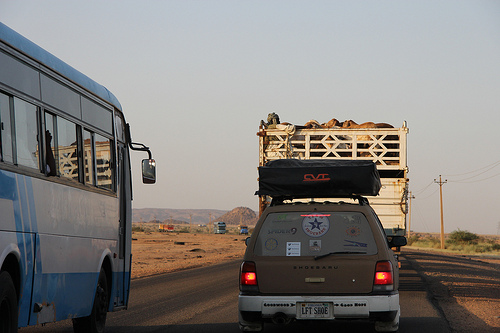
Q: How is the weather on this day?
A: It is clear.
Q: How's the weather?
A: It is clear.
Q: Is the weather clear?
A: Yes, it is clear.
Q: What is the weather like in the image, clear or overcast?
A: It is clear.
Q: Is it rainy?
A: No, it is clear.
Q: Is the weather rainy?
A: No, it is clear.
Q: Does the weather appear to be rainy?
A: No, it is clear.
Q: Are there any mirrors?
A: Yes, there is a mirror.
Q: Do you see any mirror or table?
A: Yes, there is a mirror.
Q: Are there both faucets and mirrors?
A: No, there is a mirror but no faucets.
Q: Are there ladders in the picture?
A: No, there are no ladders.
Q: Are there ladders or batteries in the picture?
A: No, there are no ladders or batteries.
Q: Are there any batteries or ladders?
A: No, there are no ladders or batteries.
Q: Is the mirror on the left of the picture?
A: Yes, the mirror is on the left of the image.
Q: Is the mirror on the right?
A: No, the mirror is on the left of the image.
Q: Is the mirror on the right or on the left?
A: The mirror is on the left of the image.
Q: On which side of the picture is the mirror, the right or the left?
A: The mirror is on the left of the image.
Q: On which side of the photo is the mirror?
A: The mirror is on the left of the image.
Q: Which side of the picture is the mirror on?
A: The mirror is on the left of the image.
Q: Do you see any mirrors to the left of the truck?
A: Yes, there is a mirror to the left of the truck.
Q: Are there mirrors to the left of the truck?
A: Yes, there is a mirror to the left of the truck.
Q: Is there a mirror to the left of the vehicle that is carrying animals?
A: Yes, there is a mirror to the left of the truck.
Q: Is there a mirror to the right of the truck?
A: No, the mirror is to the left of the truck.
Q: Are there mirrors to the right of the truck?
A: No, the mirror is to the left of the truck.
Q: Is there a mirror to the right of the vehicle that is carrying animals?
A: No, the mirror is to the left of the truck.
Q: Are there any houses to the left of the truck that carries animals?
A: No, there is a mirror to the left of the truck.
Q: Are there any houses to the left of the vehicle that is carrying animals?
A: No, there is a mirror to the left of the truck.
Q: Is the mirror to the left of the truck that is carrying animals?
A: Yes, the mirror is to the left of the truck.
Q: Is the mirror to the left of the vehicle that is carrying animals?
A: Yes, the mirror is to the left of the truck.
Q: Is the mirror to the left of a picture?
A: No, the mirror is to the left of the truck.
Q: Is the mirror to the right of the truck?
A: No, the mirror is to the left of the truck.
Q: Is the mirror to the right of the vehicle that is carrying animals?
A: No, the mirror is to the left of the truck.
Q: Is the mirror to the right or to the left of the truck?
A: The mirror is to the left of the truck.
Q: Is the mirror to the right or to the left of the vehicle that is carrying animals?
A: The mirror is to the left of the truck.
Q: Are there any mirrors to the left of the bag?
A: Yes, there is a mirror to the left of the bag.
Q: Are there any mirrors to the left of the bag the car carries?
A: Yes, there is a mirror to the left of the bag.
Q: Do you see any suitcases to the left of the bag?
A: No, there is a mirror to the left of the bag.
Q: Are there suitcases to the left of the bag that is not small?
A: No, there is a mirror to the left of the bag.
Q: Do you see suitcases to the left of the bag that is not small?
A: No, there is a mirror to the left of the bag.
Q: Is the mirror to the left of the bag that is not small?
A: Yes, the mirror is to the left of the bag.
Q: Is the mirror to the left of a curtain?
A: No, the mirror is to the left of the bag.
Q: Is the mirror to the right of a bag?
A: No, the mirror is to the left of a bag.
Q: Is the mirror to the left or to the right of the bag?
A: The mirror is to the left of the bag.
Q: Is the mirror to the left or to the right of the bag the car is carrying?
A: The mirror is to the left of the bag.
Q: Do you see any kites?
A: No, there are no kites.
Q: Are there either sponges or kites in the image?
A: No, there are no kites or sponges.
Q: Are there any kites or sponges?
A: No, there are no kites or sponges.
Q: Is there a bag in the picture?
A: Yes, there is a bag.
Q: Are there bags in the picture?
A: Yes, there is a bag.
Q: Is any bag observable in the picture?
A: Yes, there is a bag.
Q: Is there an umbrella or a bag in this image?
A: Yes, there is a bag.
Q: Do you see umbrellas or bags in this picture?
A: Yes, there is a bag.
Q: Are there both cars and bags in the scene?
A: Yes, there are both a bag and a car.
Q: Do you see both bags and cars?
A: Yes, there are both a bag and a car.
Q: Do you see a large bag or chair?
A: Yes, there is a large bag.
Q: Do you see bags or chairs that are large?
A: Yes, the bag is large.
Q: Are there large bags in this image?
A: Yes, there is a large bag.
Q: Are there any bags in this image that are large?
A: Yes, there is a bag that is large.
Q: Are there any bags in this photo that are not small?
A: Yes, there is a large bag.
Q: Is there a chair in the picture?
A: No, there are no chairs.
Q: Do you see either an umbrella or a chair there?
A: No, there are no chairs or umbrellas.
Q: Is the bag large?
A: Yes, the bag is large.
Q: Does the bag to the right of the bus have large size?
A: Yes, the bag is large.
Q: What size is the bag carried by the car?
A: The bag is large.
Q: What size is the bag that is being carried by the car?
A: The bag is large.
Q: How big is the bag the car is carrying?
A: The bag is large.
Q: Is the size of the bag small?
A: No, the bag is large.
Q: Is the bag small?
A: No, the bag is large.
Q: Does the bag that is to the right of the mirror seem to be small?
A: No, the bag is large.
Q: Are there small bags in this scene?
A: No, there is a bag but it is large.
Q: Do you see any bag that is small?
A: No, there is a bag but it is large.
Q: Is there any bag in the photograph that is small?
A: No, there is a bag but it is large.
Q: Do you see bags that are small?
A: No, there is a bag but it is large.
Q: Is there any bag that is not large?
A: No, there is a bag but it is large.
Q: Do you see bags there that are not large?
A: No, there is a bag but it is large.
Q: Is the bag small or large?
A: The bag is large.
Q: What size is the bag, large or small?
A: The bag is large.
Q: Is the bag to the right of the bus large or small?
A: The bag is large.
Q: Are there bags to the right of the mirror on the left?
A: Yes, there is a bag to the right of the mirror.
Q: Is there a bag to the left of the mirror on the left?
A: No, the bag is to the right of the mirror.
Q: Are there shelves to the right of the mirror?
A: No, there is a bag to the right of the mirror.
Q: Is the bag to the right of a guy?
A: No, the bag is to the right of a mirror.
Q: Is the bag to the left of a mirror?
A: No, the bag is to the right of a mirror.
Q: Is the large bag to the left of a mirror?
A: No, the bag is to the right of a mirror.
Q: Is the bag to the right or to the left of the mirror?
A: The bag is to the right of the mirror.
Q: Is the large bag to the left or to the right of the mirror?
A: The bag is to the right of the mirror.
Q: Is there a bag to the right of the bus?
A: Yes, there is a bag to the right of the bus.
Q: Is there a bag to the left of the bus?
A: No, the bag is to the right of the bus.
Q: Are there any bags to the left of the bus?
A: No, the bag is to the right of the bus.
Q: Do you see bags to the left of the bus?
A: No, the bag is to the right of the bus.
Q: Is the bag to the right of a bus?
A: Yes, the bag is to the right of a bus.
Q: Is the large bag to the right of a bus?
A: Yes, the bag is to the right of a bus.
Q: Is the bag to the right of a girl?
A: No, the bag is to the right of a bus.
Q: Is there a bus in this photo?
A: Yes, there is a bus.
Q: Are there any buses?
A: Yes, there is a bus.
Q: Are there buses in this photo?
A: Yes, there is a bus.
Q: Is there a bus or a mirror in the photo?
A: Yes, there is a bus.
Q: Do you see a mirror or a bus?
A: Yes, there is a bus.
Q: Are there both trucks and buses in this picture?
A: Yes, there are both a bus and a truck.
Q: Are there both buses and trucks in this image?
A: Yes, there are both a bus and a truck.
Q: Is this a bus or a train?
A: This is a bus.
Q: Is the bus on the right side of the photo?
A: No, the bus is on the left of the image.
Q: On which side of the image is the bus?
A: The bus is on the left of the image.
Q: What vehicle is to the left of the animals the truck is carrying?
A: The vehicle is a bus.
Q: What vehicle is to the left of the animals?
A: The vehicle is a bus.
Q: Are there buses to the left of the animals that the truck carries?
A: Yes, there is a bus to the left of the animals.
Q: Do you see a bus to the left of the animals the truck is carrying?
A: Yes, there is a bus to the left of the animals.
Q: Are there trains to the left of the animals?
A: No, there is a bus to the left of the animals.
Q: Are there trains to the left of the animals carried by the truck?
A: No, there is a bus to the left of the animals.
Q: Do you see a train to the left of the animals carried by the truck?
A: No, there is a bus to the left of the animals.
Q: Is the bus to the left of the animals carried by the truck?
A: Yes, the bus is to the left of the animals.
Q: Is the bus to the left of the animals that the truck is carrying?
A: Yes, the bus is to the left of the animals.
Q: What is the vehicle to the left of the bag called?
A: The vehicle is a bus.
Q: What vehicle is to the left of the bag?
A: The vehicle is a bus.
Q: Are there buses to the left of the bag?
A: Yes, there is a bus to the left of the bag.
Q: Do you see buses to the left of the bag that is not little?
A: Yes, there is a bus to the left of the bag.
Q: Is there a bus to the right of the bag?
A: No, the bus is to the left of the bag.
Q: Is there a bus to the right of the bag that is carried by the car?
A: No, the bus is to the left of the bag.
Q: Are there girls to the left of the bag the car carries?
A: No, there is a bus to the left of the bag.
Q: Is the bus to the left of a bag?
A: Yes, the bus is to the left of a bag.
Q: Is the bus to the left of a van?
A: No, the bus is to the left of a bag.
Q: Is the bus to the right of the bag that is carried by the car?
A: No, the bus is to the left of the bag.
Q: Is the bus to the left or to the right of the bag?
A: The bus is to the left of the bag.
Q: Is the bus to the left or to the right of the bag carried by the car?
A: The bus is to the left of the bag.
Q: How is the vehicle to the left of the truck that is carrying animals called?
A: The vehicle is a bus.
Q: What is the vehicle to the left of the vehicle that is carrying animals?
A: The vehicle is a bus.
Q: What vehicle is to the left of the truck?
A: The vehicle is a bus.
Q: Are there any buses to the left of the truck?
A: Yes, there is a bus to the left of the truck.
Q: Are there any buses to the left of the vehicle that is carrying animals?
A: Yes, there is a bus to the left of the truck.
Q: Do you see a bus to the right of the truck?
A: No, the bus is to the left of the truck.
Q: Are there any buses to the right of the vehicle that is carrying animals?
A: No, the bus is to the left of the truck.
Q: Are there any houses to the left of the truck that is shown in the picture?
A: No, there is a bus to the left of the truck.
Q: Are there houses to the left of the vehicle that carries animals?
A: No, there is a bus to the left of the truck.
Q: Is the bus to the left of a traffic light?
A: No, the bus is to the left of the truck.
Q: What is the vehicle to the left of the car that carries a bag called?
A: The vehicle is a bus.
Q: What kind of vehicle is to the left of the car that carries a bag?
A: The vehicle is a bus.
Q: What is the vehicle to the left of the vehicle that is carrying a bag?
A: The vehicle is a bus.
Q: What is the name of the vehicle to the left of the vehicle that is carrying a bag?
A: The vehicle is a bus.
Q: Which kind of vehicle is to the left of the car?
A: The vehicle is a bus.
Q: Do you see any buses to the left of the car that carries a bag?
A: Yes, there is a bus to the left of the car.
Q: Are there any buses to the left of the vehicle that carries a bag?
A: Yes, there is a bus to the left of the car.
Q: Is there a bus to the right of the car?
A: No, the bus is to the left of the car.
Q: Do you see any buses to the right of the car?
A: No, the bus is to the left of the car.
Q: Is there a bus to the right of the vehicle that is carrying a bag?
A: No, the bus is to the left of the car.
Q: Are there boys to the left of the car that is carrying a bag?
A: No, there is a bus to the left of the car.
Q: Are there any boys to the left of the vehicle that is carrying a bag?
A: No, there is a bus to the left of the car.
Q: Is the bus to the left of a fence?
A: No, the bus is to the left of the car.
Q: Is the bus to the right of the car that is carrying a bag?
A: No, the bus is to the left of the car.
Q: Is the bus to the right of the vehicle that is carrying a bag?
A: No, the bus is to the left of the car.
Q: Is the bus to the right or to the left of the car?
A: The bus is to the left of the car.